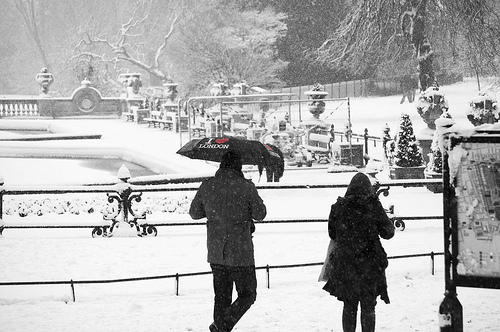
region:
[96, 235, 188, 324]
there is snow on the ground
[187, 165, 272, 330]
the guy has an umbrella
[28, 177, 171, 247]
the rails are black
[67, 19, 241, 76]
the trees have snow on it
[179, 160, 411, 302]
the people aretwo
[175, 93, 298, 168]
the umbrella is black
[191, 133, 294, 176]
the words are i love london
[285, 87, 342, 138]
the sculpture has snow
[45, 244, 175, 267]
the snow is white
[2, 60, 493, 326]
the photo was taken out doors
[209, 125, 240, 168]
Red heart on umbrella.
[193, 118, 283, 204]
I love london written on umbrella.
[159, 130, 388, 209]
Umbrella is black in color.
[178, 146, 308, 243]
Person holding umbrella.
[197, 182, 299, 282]
Person wearing dark jacket.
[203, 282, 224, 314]
Person wearing dark pants.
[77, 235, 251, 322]
Snow covering ground.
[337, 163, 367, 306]
Person wearing dark jacket.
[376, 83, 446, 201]
Tree covered in snow.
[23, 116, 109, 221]
Water is covered in snow.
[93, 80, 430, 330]
a man with an umbrella to protect himself from snow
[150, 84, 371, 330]
a man with a black and red umbrella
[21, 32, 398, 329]
snowy winter wonderland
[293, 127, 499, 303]
a woman staring at the snow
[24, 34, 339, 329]
no one but these three people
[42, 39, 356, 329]
snow covering the area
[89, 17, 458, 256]
bare trees with snow on them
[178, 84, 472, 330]
man and woman wearing black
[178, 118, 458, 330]
people in coats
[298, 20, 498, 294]
everything is covered in snow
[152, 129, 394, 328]
two people walking in the snow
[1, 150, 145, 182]
a pond in the middle of the park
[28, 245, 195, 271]
the snow is bright white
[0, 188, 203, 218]
the bench is covered in snow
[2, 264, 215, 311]
the railing is black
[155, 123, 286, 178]
the man holds an umbrella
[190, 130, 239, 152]
the umbrella says i heart london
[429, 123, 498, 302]
a map of the area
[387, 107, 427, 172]
the trees have snow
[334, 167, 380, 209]
the lady has her coat hood on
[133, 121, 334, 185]
red heart only color in picture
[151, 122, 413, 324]
two people standing in snow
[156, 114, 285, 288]
man holding umbrella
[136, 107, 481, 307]
two people in snowstorm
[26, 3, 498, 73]
snow covered trees in background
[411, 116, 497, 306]
snow on sign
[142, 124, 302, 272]
umbrella says I hear London in white letters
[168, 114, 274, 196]
umbrella has red heart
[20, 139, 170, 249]
looks like a snow covered pond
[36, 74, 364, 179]
snow covered benches